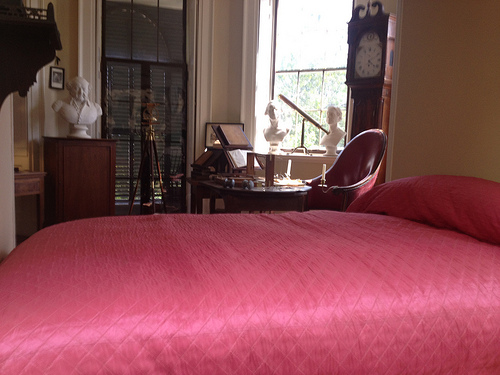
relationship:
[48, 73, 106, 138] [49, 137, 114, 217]
man on table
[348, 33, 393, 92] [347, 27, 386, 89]
clock face on clock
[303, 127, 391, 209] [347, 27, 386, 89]
chair near clock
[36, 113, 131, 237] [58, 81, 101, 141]
stand near statue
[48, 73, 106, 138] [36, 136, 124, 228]
man on stand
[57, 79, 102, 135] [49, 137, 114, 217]
bust on table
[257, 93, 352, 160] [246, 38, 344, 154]
busts on window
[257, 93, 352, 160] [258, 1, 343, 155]
busts on window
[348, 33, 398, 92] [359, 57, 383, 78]
clock face reading 6;22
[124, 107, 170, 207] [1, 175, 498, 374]
tripod near bed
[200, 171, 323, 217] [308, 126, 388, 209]
table near chair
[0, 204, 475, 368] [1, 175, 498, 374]
blanket on bed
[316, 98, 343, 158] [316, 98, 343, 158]
statue on statue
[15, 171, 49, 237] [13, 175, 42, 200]
nightstand with drawer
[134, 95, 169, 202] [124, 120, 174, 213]
telescope on tripod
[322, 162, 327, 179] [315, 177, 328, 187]
white candle in candle holder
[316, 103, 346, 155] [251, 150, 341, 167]
bust resting on wooden sill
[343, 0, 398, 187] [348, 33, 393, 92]
grandfather clock with clock face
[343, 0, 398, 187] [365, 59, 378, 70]
grandfather clock with hands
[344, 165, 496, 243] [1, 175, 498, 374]
pillow at bed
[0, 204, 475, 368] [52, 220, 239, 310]
blanket with design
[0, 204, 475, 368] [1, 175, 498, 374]
blanket covering bed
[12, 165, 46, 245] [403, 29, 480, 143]
stand in front of wall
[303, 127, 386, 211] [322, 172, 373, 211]
chair with arm rest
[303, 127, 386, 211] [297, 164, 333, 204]
chair with arm rest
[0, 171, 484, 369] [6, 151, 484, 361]
blanket on bed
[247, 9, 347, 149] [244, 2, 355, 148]
sun coming window